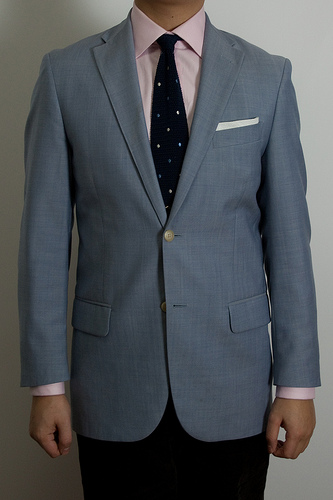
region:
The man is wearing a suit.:
[17, 3, 314, 492]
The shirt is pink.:
[116, 6, 236, 239]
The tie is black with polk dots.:
[146, 28, 189, 228]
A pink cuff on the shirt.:
[20, 380, 73, 401]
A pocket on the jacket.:
[64, 288, 117, 350]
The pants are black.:
[69, 394, 282, 498]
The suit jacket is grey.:
[22, 24, 306, 445]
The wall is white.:
[9, 11, 111, 25]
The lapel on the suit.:
[88, 34, 177, 217]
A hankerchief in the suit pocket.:
[217, 103, 270, 149]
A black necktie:
[134, 36, 211, 209]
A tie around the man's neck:
[116, 0, 227, 174]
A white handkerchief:
[208, 112, 265, 134]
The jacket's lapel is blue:
[98, 22, 222, 217]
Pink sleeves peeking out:
[32, 378, 66, 400]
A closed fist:
[24, 406, 85, 460]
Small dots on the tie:
[142, 58, 197, 204]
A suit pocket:
[220, 282, 283, 339]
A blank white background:
[272, 24, 317, 53]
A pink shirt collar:
[127, 9, 224, 60]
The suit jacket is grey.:
[22, 4, 308, 457]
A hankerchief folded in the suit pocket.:
[211, 99, 263, 149]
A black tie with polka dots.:
[128, 22, 212, 218]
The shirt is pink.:
[115, 4, 243, 244]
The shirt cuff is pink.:
[272, 380, 317, 407]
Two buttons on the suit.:
[143, 215, 193, 345]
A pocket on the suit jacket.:
[68, 289, 115, 359]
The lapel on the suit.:
[84, 10, 152, 239]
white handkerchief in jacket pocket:
[204, 110, 267, 142]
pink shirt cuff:
[271, 382, 320, 405]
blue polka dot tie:
[133, 26, 201, 212]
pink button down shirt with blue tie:
[126, 7, 215, 81]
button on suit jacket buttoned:
[157, 225, 181, 245]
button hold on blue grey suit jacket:
[168, 299, 189, 311]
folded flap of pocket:
[69, 296, 116, 338]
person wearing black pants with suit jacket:
[77, 417, 274, 497]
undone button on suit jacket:
[156, 297, 168, 311]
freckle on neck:
[169, 11, 178, 20]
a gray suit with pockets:
[14, 19, 327, 454]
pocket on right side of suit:
[214, 289, 279, 343]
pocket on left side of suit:
[64, 295, 117, 352]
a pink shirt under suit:
[4, 6, 331, 412]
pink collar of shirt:
[126, 10, 208, 58]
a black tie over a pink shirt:
[146, 30, 195, 216]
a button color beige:
[158, 224, 178, 245]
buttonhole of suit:
[164, 296, 192, 316]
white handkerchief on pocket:
[208, 110, 268, 139]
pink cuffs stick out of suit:
[17, 367, 329, 411]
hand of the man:
[239, 389, 323, 478]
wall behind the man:
[288, 455, 326, 498]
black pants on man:
[59, 419, 271, 499]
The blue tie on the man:
[146, 32, 189, 215]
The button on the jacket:
[162, 229, 175, 242]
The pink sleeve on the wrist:
[27, 380, 66, 395]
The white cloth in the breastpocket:
[214, 115, 260, 129]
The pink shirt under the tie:
[129, 3, 207, 140]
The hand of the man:
[266, 399, 319, 459]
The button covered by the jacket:
[160, 302, 166, 310]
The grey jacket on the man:
[14, 5, 320, 442]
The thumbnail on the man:
[265, 444, 272, 454]